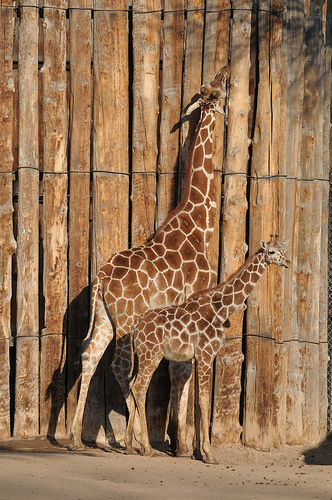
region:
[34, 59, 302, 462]
two giraffes standing in the dirt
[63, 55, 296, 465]
a baby giraffe next to an adult giraffe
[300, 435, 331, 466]
shadow on the ground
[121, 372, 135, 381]
black hair on the bottom of the tail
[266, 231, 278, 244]
two small horns on the top of the head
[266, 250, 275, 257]
eye on the side of the head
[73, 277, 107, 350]
tail hanging down towards the ground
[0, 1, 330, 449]
tall wooden posts on the fence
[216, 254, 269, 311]
brown spots along the neck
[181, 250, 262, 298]
hair along the neck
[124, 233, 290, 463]
Baby giraffe standing near fence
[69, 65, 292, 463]
Mother and baby giraffe standing together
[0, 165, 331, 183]
Seam in middle of wooden fence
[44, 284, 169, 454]
Shadow of giraffes on fence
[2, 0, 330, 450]
Rough fence made of wooden poles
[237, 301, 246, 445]
Gap in bottom of wooden fence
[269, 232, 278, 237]
Dark tips on horns on giraffe's head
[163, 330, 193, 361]
Full belly underneath baby giraffe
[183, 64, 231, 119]
Adult giraffe's head facing fence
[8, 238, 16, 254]
Bump on wooden pole of fence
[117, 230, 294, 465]
Baby giraffe in the forefront.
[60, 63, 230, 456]
Adult giraffe behind the baby.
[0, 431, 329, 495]
Dirt covering the ground.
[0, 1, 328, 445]
Fence behind the giraffe.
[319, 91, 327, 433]
chain link fence behind the wood.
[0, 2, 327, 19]
Wire on the fence.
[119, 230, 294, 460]
Brown spots on the giraffe.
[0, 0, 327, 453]
wood logs creating the fence.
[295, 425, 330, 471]
shadow on the ground.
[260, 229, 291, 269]
Horns on the giraffe's head.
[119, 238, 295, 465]
a baby giraffe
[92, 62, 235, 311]
a giraffe stretching its neck up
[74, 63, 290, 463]
two giraffes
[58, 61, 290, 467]
a baby giraffe standing in front of its mother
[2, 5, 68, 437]
tall fence made out of logs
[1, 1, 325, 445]
tall wooden fence that is part of a giraffe enclosure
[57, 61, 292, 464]
giraffes in captivity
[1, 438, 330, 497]
dirt ground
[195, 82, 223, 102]
horns on a giraffe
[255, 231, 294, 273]
the head of a giraffe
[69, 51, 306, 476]
giraffes standing on ground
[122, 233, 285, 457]
smaller giraffe on ground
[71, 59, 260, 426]
larger giraffe on ground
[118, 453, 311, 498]
rocks on the ground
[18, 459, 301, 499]
ground elephants stand on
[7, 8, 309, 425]
wall made of logs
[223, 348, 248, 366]
knobs on the wood wall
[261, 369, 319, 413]
variation in wood color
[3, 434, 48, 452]
dirt on the ground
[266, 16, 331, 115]
shade from a tree